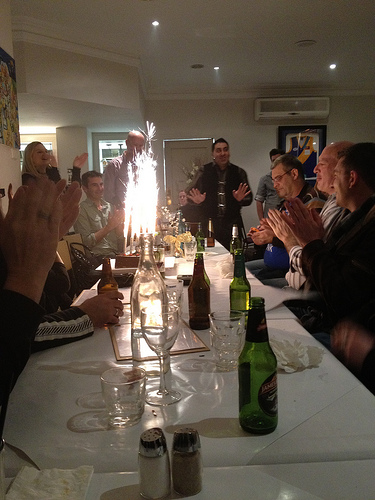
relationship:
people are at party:
[45, 140, 357, 280] [13, 106, 368, 451]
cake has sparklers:
[117, 245, 166, 275] [123, 117, 163, 249]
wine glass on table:
[136, 303, 186, 410] [3, 231, 365, 496]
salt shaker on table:
[133, 430, 171, 498] [3, 231, 365, 496]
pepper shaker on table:
[170, 429, 204, 494] [3, 231, 365, 496]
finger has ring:
[108, 306, 127, 318] [114, 308, 119, 320]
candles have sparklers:
[122, 231, 156, 254] [123, 117, 163, 249]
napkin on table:
[263, 340, 327, 374] [3, 231, 365, 496]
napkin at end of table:
[263, 340, 327, 374] [3, 231, 365, 496]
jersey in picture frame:
[280, 129, 320, 176] [275, 122, 333, 184]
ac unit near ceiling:
[251, 93, 334, 125] [13, 8, 368, 92]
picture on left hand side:
[1, 47, 23, 147] [16, 4, 154, 319]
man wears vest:
[180, 134, 257, 233] [200, 167, 248, 222]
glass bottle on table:
[230, 295, 288, 434] [3, 231, 365, 496]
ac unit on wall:
[251, 93, 334, 125] [154, 106, 368, 150]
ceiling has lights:
[13, 8, 368, 92] [152, 17, 342, 75]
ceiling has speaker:
[13, 8, 368, 92] [188, 60, 213, 76]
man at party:
[180, 134, 257, 233] [13, 106, 368, 451]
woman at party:
[18, 140, 96, 179] [13, 106, 368, 451]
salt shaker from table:
[133, 430, 171, 498] [3, 231, 365, 496]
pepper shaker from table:
[170, 429, 204, 494] [3, 231, 365, 496]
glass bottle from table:
[230, 295, 288, 434] [3, 231, 365, 496]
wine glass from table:
[136, 303, 186, 410] [3, 231, 365, 496]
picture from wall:
[1, 47, 23, 147] [4, 14, 16, 194]